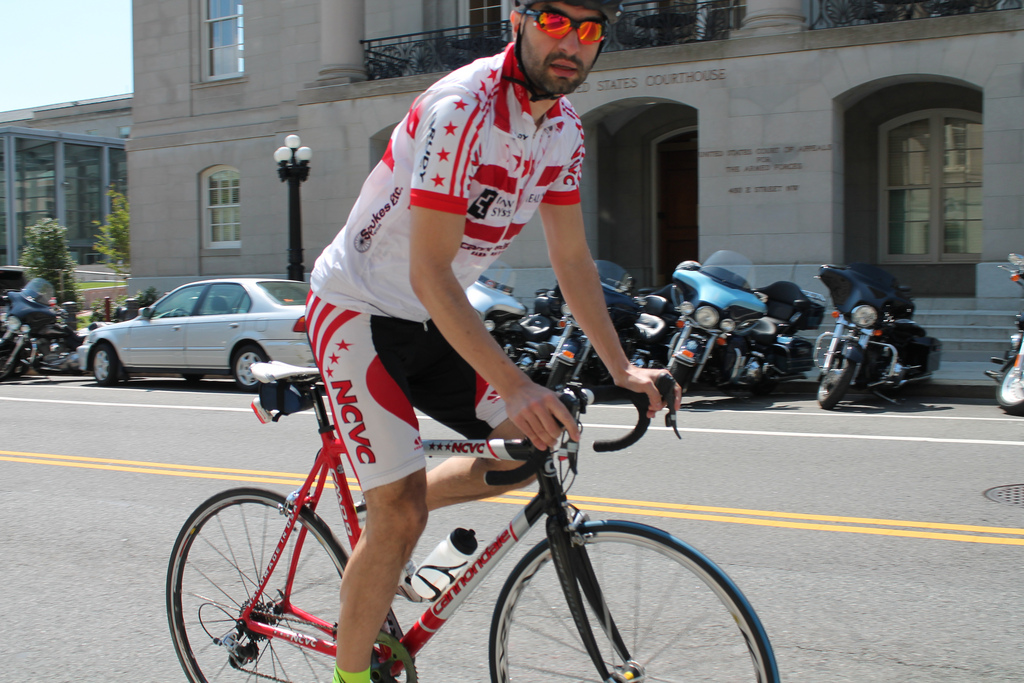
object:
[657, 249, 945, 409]
motorcycles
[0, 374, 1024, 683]
street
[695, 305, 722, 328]
headlight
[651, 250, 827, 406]
motorcycle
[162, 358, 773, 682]
bicycle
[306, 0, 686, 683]
man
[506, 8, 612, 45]
glasses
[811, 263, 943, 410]
motorcycle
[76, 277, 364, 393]
car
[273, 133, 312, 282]
lamp pole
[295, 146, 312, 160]
light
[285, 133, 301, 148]
light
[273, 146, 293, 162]
light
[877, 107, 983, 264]
large window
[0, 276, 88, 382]
motorcycle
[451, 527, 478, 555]
black cap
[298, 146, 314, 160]
street lamp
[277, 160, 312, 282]
metal pole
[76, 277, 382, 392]
silver car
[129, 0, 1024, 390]
courthouse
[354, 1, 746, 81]
railing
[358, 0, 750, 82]
balcony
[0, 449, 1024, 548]
yellow lines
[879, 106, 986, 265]
window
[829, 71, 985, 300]
arch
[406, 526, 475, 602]
water bottle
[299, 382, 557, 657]
bicycle frame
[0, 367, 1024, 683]
line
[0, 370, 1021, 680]
street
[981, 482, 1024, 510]
manhole cover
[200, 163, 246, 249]
window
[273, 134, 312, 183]
street lamps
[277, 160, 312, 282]
pole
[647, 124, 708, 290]
door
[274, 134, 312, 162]
light covers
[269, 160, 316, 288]
pole